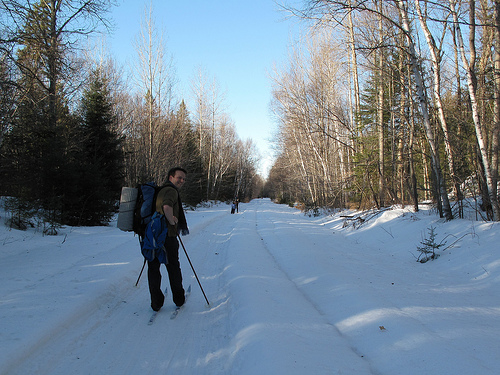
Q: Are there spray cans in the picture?
A: No, there are no spray cans.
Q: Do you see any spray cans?
A: No, there are no spray cans.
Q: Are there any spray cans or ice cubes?
A: No, there are no spray cans or ice cubes.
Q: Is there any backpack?
A: Yes, there is a backpack.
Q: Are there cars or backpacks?
A: Yes, there is a backpack.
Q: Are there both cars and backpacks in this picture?
A: No, there is a backpack but no cars.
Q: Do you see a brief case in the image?
A: No, there are no briefcases.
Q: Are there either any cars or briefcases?
A: No, there are no briefcases or cars.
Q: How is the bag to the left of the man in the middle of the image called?
A: The bag is a backpack.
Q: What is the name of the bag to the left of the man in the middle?
A: The bag is a backpack.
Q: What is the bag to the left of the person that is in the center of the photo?
A: The bag is a backpack.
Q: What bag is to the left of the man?
A: The bag is a backpack.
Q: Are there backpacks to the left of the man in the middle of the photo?
A: Yes, there is a backpack to the left of the man.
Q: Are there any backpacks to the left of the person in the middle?
A: Yes, there is a backpack to the left of the man.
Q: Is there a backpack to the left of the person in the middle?
A: Yes, there is a backpack to the left of the man.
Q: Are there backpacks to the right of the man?
A: No, the backpack is to the left of the man.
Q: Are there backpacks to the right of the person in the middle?
A: No, the backpack is to the left of the man.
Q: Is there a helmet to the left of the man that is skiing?
A: No, there is a backpack to the left of the man.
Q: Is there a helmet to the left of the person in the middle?
A: No, there is a backpack to the left of the man.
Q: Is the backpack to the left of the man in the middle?
A: Yes, the backpack is to the left of the man.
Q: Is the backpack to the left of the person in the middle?
A: Yes, the backpack is to the left of the man.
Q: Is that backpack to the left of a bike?
A: No, the backpack is to the left of the man.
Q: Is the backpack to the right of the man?
A: No, the backpack is to the left of the man.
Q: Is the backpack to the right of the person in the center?
A: No, the backpack is to the left of the man.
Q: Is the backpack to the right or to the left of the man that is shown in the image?
A: The backpack is to the left of the man.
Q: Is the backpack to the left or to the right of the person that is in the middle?
A: The backpack is to the left of the man.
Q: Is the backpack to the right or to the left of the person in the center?
A: The backpack is to the left of the man.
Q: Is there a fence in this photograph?
A: No, there are no fences.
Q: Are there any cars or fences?
A: No, there are no fences or cars.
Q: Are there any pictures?
A: No, there are no pictures.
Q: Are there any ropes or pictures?
A: No, there are no pictures or ropes.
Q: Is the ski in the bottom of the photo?
A: Yes, the ski is in the bottom of the image.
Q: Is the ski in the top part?
A: No, the ski is in the bottom of the image.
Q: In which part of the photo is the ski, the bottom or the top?
A: The ski is in the bottom of the image.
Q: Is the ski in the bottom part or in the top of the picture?
A: The ski is in the bottom of the image.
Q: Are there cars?
A: No, there are no cars.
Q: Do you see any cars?
A: No, there are no cars.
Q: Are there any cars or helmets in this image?
A: No, there are no cars or helmets.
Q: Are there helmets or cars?
A: No, there are no cars or helmets.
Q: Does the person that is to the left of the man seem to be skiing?
A: Yes, the person is skiing.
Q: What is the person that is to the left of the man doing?
A: The person is skiing.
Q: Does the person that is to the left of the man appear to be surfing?
A: No, the person is skiing.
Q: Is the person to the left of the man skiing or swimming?
A: The person is skiing.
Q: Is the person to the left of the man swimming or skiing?
A: The person is skiing.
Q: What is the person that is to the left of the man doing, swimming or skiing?
A: The person is skiing.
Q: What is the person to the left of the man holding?
A: The person is holding the pole.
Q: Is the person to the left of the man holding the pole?
A: Yes, the person is holding the pole.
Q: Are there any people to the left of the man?
A: Yes, there is a person to the left of the man.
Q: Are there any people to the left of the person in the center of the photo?
A: Yes, there is a person to the left of the man.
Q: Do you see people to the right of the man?
A: No, the person is to the left of the man.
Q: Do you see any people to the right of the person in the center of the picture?
A: No, the person is to the left of the man.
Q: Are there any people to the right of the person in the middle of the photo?
A: No, the person is to the left of the man.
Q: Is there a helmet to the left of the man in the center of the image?
A: No, there is a person to the left of the man.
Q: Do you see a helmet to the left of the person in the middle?
A: No, there is a person to the left of the man.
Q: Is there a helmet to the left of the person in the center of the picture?
A: No, there is a person to the left of the man.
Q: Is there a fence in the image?
A: No, there are no fences.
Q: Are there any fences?
A: No, there are no fences.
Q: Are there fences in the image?
A: No, there are no fences.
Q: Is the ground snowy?
A: Yes, the ground is snowy.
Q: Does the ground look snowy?
A: Yes, the ground is snowy.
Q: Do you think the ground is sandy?
A: No, the ground is snowy.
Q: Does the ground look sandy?
A: No, the ground is snowy.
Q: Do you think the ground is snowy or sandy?
A: The ground is snowy.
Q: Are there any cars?
A: No, there are no cars.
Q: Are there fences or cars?
A: No, there are no cars or fences.